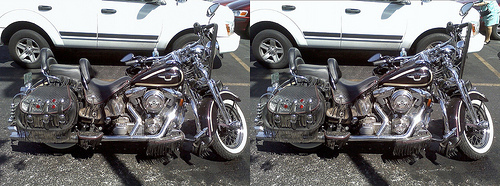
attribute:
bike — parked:
[8, 4, 248, 161]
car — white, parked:
[1, 1, 240, 69]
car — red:
[227, 1, 252, 37]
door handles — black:
[99, 8, 118, 14]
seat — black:
[41, 46, 131, 102]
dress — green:
[478, 1, 500, 27]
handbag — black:
[476, 1, 490, 16]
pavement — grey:
[0, 38, 499, 185]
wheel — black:
[210, 98, 249, 159]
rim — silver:
[17, 37, 41, 62]